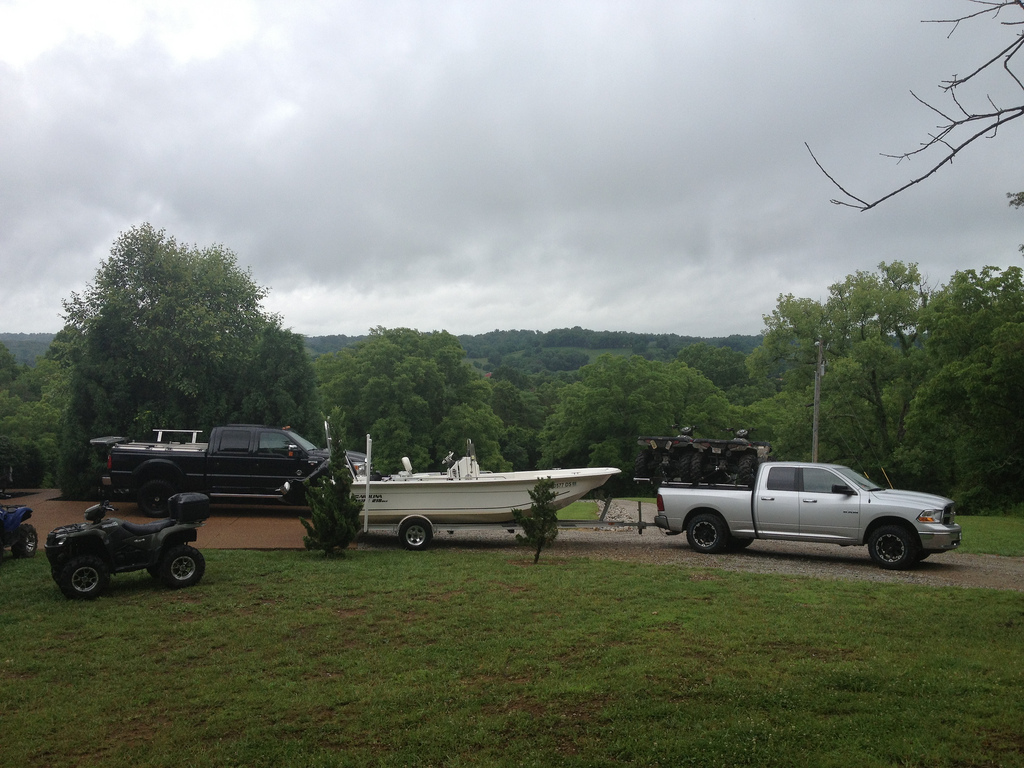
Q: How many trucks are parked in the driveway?
A: Two.